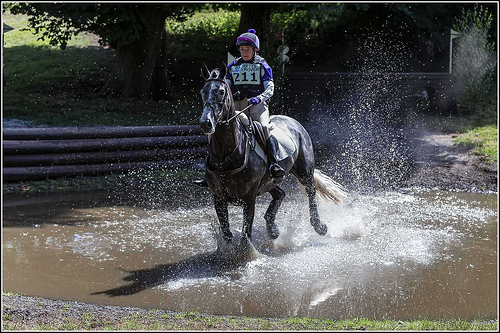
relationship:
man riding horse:
[219, 26, 286, 184] [199, 61, 350, 248]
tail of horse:
[313, 168, 340, 204] [199, 61, 350, 248]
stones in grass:
[5, 296, 154, 330] [3, 298, 483, 329]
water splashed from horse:
[54, 58, 481, 310] [193, 60, 328, 237]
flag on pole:
[446, 27, 460, 77] [448, 41, 454, 71]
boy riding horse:
[193, 29, 284, 188] [199, 61, 350, 248]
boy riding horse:
[193, 29, 284, 188] [192, 75, 349, 260]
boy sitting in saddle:
[213, 25, 295, 114] [228, 110, 308, 144]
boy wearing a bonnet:
[193, 29, 284, 188] [236, 29, 260, 52]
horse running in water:
[199, 61, 350, 248] [6, 185, 497, 317]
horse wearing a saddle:
[199, 61, 350, 248] [242, 113, 298, 165]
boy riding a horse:
[193, 29, 284, 188] [199, 61, 350, 248]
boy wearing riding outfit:
[193, 29, 284, 188] [189, 46, 316, 118]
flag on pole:
[449, 29, 461, 74] [449, 40, 453, 71]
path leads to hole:
[388, 109, 483, 199] [10, 191, 484, 325]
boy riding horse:
[193, 29, 284, 188] [191, 61, 343, 249]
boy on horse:
[193, 29, 284, 188] [199, 61, 350, 248]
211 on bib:
[233, 72, 257, 82] [228, 57, 262, 85]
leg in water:
[262, 185, 291, 246] [2, 190, 483, 331]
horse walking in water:
[201, 67, 328, 250] [8, 172, 498, 321]